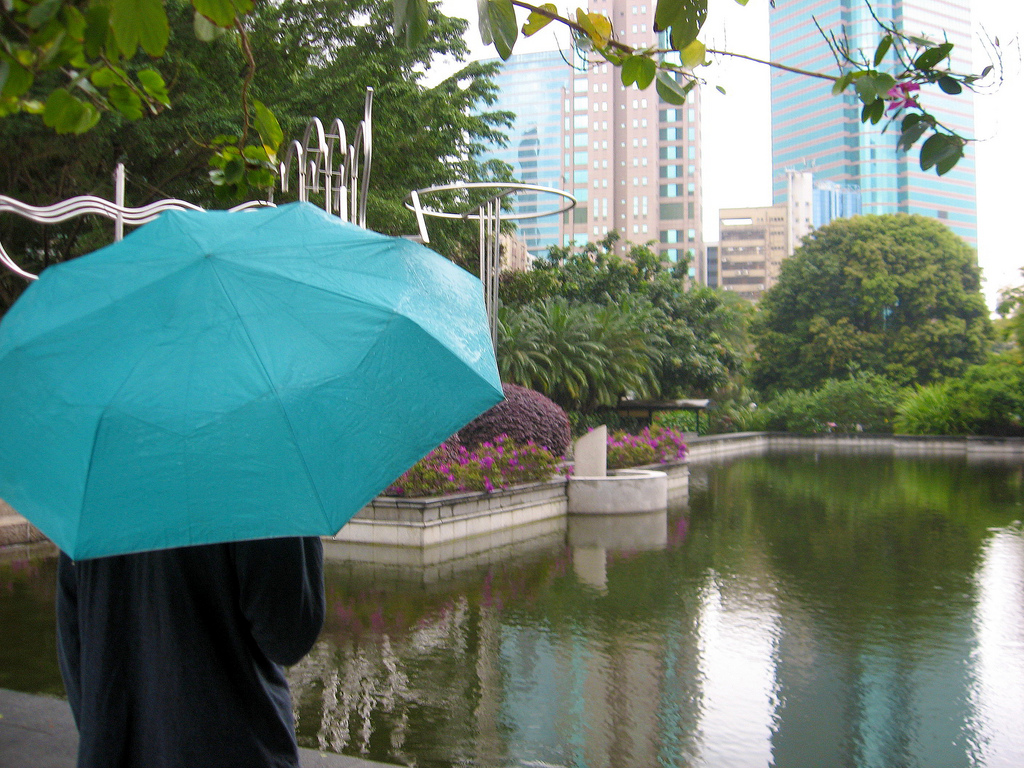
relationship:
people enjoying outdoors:
[11, 474, 344, 764] [0, 11, 943, 763]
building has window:
[514, 5, 716, 317] [659, 161, 692, 181]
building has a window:
[454, 29, 990, 339] [560, 163, 595, 220]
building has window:
[561, 3, 704, 299] [639, 118, 652, 131]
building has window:
[561, 3, 704, 299] [659, 128, 685, 148]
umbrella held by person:
[10, 198, 507, 566] [51, 532, 324, 762]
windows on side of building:
[715, 212, 763, 286] [712, 203, 788, 316]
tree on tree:
[0, 0, 517, 314] [0, 0, 517, 314]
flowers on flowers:
[479, 382, 568, 447] [458, 382, 571, 456]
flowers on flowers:
[606, 423, 695, 454] [607, 423, 690, 468]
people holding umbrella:
[53, 500, 328, 768] [10, 198, 507, 566]